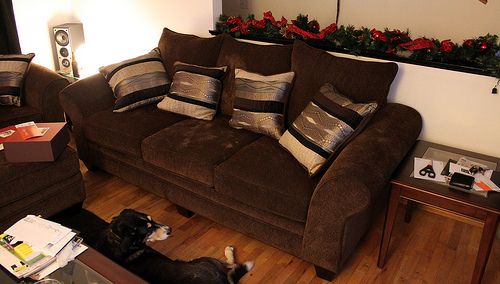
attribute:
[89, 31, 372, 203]
pillows — striped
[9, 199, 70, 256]
books — stacked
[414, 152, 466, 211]
scissors — black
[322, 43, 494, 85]
flowers — red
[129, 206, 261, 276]
dog — black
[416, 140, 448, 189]
scissors — black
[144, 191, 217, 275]
dog — black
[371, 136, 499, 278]
end table — wooden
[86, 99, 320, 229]
cushions — brown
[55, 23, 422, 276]
couch — brown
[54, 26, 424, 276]
sofa — brown, plush, dark brown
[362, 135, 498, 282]
table — wood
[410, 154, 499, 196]
papers — white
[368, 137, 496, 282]
side table — wooden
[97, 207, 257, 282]
dog — black, brown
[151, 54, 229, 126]
throw pillow — black, silver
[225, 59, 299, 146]
throw pillow — silver, black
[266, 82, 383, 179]
throw pillow — black, silver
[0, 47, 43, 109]
throw pillow — silver, black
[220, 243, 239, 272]
foot — white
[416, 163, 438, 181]
handles — black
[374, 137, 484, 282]
table — wooden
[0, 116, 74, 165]
box — cardboard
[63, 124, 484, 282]
floors — hardwood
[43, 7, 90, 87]
speaker — black, silver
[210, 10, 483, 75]
garland — green, red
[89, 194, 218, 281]
dog — black, brown